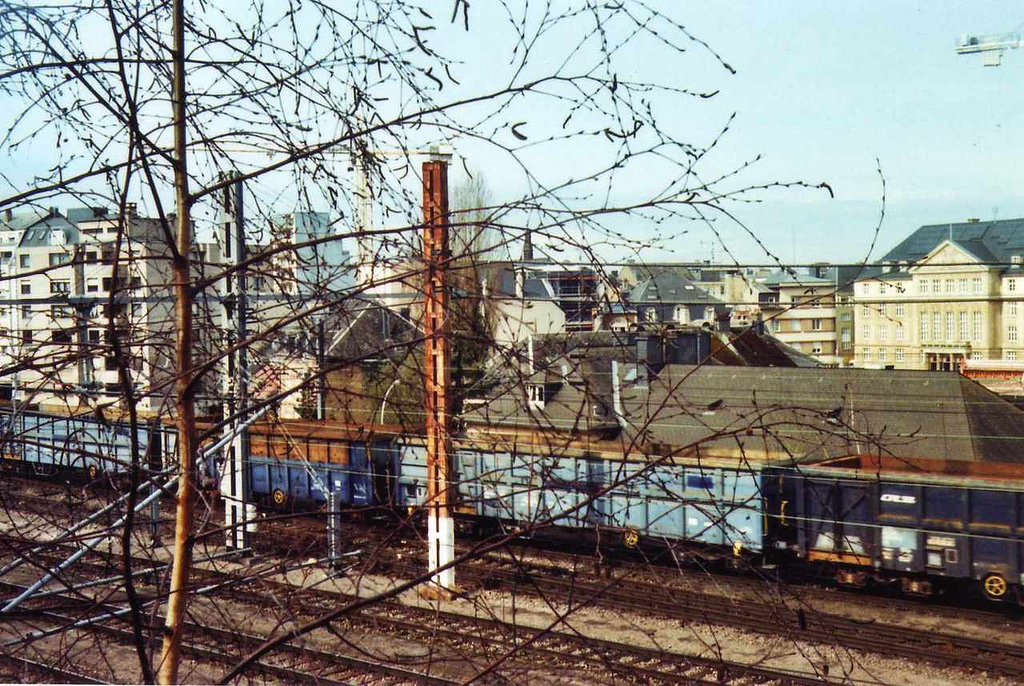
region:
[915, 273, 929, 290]
a window on a building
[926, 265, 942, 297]
a window on a building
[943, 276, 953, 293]
a window on a building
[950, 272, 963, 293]
a window on a building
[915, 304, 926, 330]
a window on a building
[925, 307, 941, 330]
a window on a building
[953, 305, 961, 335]
a window on a building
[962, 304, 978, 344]
a window on a building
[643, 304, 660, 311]
a window on a building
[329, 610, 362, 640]
branch on the tree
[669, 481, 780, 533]
branch on the tree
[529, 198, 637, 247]
branch on the tree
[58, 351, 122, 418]
branch on the tree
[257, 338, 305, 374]
branch on the tree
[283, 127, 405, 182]
branch on the tree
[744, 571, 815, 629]
branch on the tree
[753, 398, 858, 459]
branch on the tree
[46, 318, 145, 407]
branch on the tree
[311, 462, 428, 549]
branch on the tree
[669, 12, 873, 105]
grey and white sky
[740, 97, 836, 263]
clouds are faint white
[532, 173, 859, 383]
power lines in air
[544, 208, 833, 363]
power lines are black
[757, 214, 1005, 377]
large and white building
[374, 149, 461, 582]
brown and metal tower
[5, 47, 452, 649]
brown and bare tree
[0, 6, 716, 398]
tree has no leaves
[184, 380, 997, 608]
train on brown track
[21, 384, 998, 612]
train on the tracks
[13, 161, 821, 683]
tree and branches in front of the train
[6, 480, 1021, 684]
tracks without trains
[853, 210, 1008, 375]
beige building with green roof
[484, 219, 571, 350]
building with spire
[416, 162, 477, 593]
rusty pole next to train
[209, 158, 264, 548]
silver pole next to the train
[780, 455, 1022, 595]
navy blue train car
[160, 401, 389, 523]
blue and brown train car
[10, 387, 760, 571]
two light blue train cars